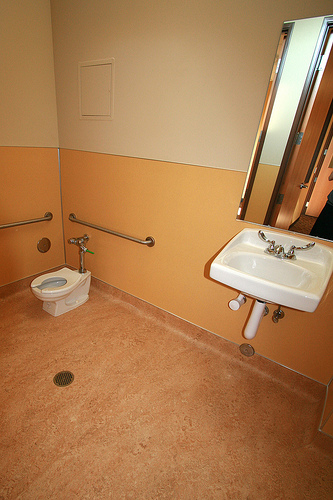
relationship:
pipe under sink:
[242, 297, 269, 341] [208, 227, 332, 313]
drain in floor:
[52, 370, 75, 388] [0, 280, 332, 500]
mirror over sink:
[236, 14, 332, 242] [208, 227, 332, 313]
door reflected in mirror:
[268, 26, 333, 230] [236, 14, 332, 242]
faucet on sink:
[274, 245, 296, 261] [208, 227, 332, 313]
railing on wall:
[67, 212, 155, 248] [1, 0, 332, 384]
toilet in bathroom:
[30, 267, 91, 318] [0, 0, 332, 499]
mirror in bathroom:
[236, 14, 332, 242] [0, 0, 332, 499]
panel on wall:
[77, 56, 116, 121] [1, 0, 332, 384]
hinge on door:
[294, 132, 304, 147] [268, 26, 333, 230]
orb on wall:
[238, 343, 255, 358] [1, 0, 332, 384]